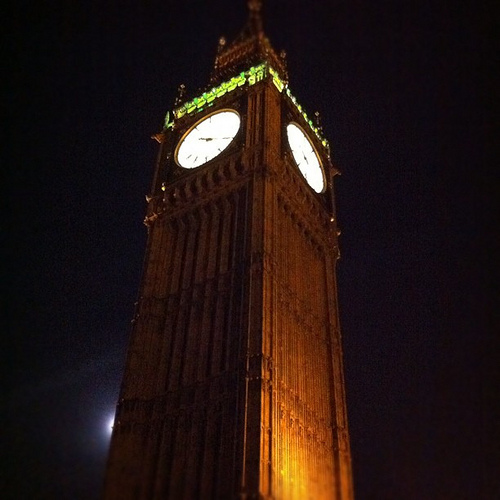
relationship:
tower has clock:
[99, 0, 355, 499] [172, 108, 240, 168]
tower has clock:
[99, 0, 355, 499] [286, 121, 328, 194]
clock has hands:
[172, 108, 240, 168] [196, 133, 231, 142]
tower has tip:
[99, 0, 355, 499] [212, 0, 289, 85]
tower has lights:
[99, 0, 355, 499] [174, 62, 266, 120]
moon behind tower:
[104, 412, 116, 444] [99, 0, 355, 499]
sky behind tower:
[2, 2, 497, 499] [99, 0, 355, 499]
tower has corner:
[99, 0, 355, 499] [258, 57, 274, 82]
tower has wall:
[99, 0, 355, 499] [100, 157, 259, 495]